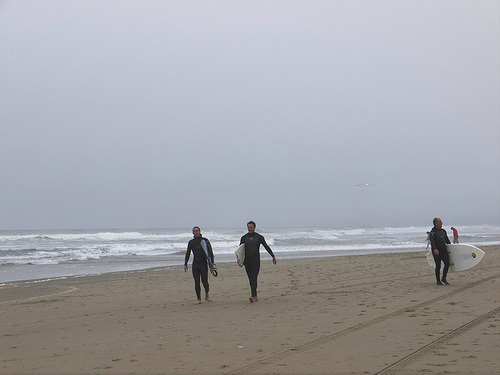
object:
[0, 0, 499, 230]
sky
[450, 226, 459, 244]
person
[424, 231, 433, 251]
person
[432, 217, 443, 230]
head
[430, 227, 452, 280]
wet suit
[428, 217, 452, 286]
man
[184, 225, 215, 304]
man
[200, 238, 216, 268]
surfboard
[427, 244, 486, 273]
surfboard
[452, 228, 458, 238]
jacket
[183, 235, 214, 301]
suit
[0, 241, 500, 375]
beach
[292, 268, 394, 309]
footprints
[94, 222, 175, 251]
waves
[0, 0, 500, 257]
background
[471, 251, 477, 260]
emblem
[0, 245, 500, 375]
sand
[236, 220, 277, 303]
man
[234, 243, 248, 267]
surfboard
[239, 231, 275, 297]
wetsuit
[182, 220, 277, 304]
two men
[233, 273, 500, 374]
tire tracks